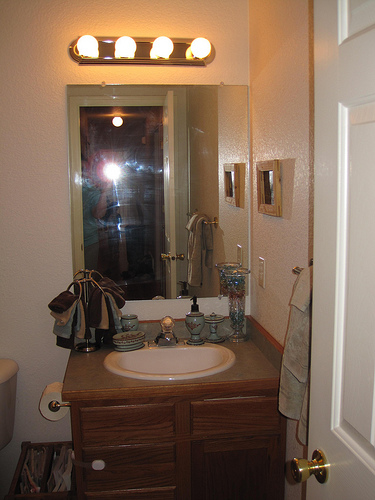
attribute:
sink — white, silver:
[104, 339, 236, 381]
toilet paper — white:
[40, 383, 69, 421]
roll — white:
[49, 401, 62, 413]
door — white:
[306, 0, 373, 499]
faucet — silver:
[156, 318, 177, 347]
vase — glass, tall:
[223, 266, 250, 341]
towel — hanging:
[279, 266, 311, 448]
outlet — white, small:
[256, 258, 266, 290]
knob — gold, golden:
[290, 451, 329, 485]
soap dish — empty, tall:
[114, 332, 146, 353]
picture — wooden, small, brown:
[255, 161, 284, 218]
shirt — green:
[101, 199, 141, 276]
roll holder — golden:
[49, 402, 70, 411]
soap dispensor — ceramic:
[111, 329, 146, 353]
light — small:
[191, 37, 212, 61]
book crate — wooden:
[8, 441, 76, 499]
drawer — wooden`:
[78, 404, 176, 444]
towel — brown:
[48, 293, 85, 312]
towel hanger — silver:
[290, 265, 303, 276]